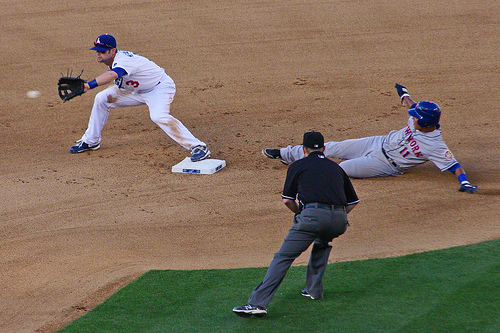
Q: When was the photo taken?
A: Day time.